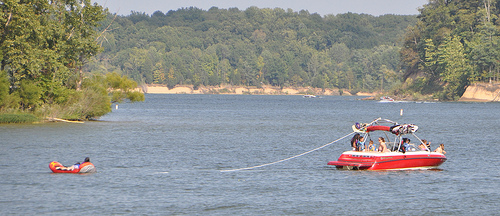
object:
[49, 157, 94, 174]
float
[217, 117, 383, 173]
rope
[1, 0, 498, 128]
forest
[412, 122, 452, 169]
ground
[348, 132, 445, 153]
people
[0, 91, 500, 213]
water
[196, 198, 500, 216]
ripples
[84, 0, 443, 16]
clouds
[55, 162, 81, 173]
object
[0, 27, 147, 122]
bush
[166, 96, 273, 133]
river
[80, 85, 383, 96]
dry terrain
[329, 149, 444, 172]
float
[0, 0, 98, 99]
leaves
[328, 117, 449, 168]
boat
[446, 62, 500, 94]
bush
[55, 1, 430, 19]
sky